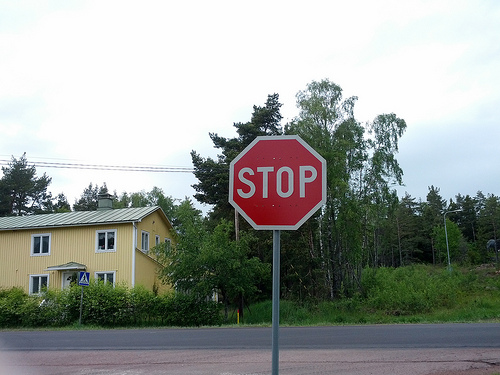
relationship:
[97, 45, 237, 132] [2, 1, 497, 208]
clouds in sky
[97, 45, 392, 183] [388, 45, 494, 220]
clouds in sky